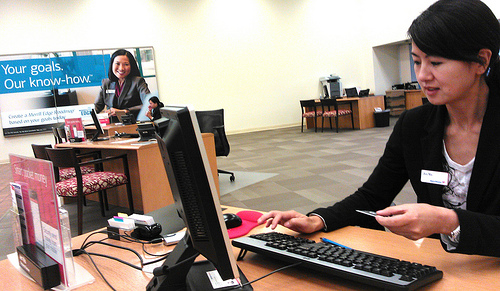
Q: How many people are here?
A: 2.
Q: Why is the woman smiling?
A: She is happy.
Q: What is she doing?
A: Typing.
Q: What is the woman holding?
A: A card.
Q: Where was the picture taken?
A: At an office.